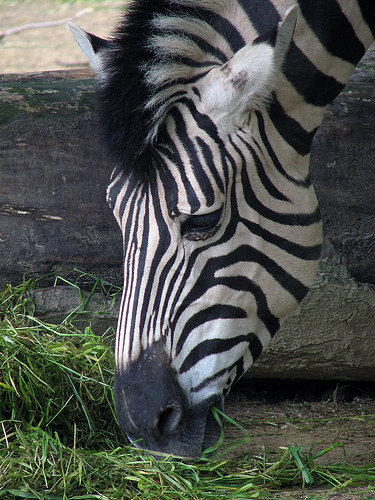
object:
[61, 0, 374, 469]
zebra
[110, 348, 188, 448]
nose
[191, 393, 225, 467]
mouth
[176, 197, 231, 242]
eye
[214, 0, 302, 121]
ear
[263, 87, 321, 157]
stripe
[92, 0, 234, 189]
mane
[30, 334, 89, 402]
grass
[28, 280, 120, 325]
stump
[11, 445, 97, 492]
ground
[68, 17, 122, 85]
ears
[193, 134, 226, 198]
stripes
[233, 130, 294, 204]
strips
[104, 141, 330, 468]
face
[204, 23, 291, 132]
hair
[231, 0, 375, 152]
neck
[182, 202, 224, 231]
hair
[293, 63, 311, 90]
hair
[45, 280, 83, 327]
rock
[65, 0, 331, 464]
head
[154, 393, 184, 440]
nostril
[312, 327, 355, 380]
dirt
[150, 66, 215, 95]
spot